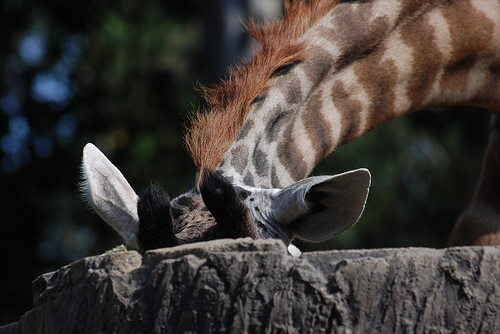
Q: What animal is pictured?
A: Giraffe.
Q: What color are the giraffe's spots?
A: Brown.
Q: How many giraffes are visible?
A: 1.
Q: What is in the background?
A: Trees.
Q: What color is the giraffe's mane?
A: Orange.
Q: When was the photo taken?
A: During the day.